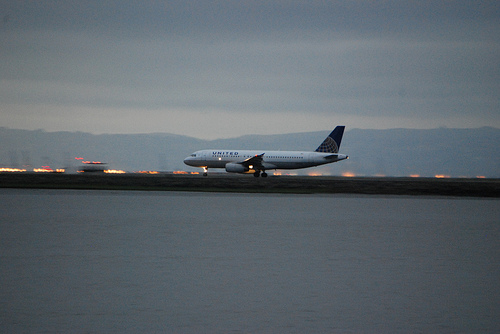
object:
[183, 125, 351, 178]
plane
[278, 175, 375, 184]
tarmac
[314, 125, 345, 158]
tail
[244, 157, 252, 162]
small lights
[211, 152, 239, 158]
logo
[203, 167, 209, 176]
front wheel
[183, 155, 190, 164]
nose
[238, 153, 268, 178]
dark wing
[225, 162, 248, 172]
jet engine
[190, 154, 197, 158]
cockpit windows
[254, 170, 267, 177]
rear wheels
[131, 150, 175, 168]
background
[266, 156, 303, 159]
windows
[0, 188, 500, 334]
small lake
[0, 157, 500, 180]
airport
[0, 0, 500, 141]
sky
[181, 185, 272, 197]
shore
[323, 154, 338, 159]
back wing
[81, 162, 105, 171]
building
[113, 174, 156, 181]
field